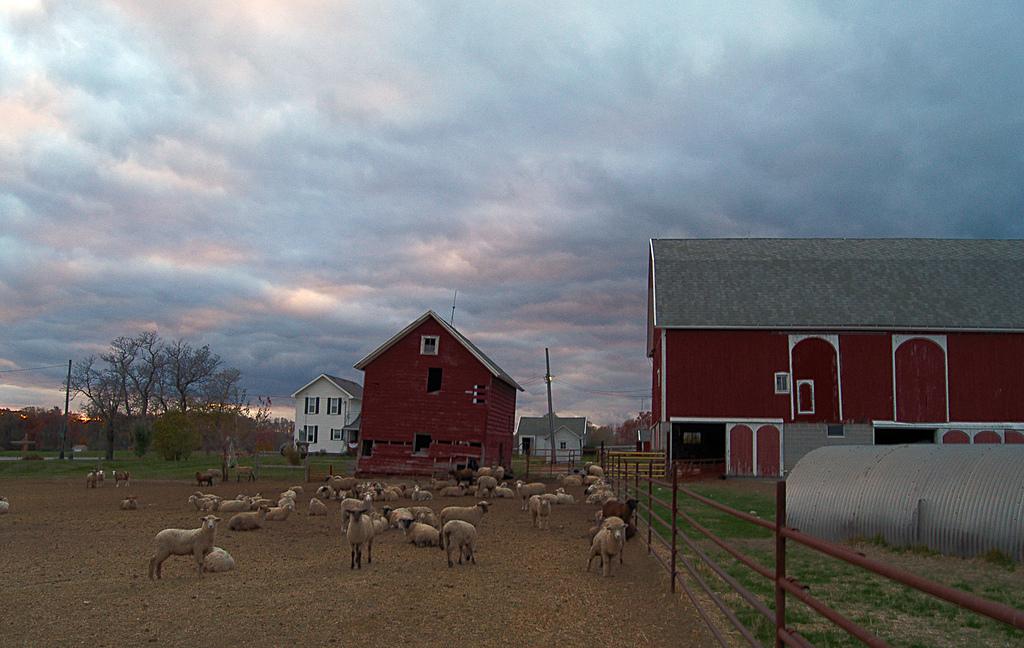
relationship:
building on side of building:
[353, 309, 525, 478] [336, 301, 511, 483]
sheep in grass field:
[112, 499, 251, 597] [28, 475, 629, 644]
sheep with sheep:
[213, 504, 268, 535] [228, 505, 271, 531]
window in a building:
[417, 332, 441, 361] [350, 306, 510, 475]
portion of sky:
[292, 293, 340, 320] [11, 12, 610, 306]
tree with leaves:
[158, 353, 215, 472] [197, 347, 217, 371]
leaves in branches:
[197, 347, 217, 371] [179, 369, 240, 408]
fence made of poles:
[624, 446, 990, 643] [655, 472, 789, 626]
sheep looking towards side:
[140, 513, 231, 578] [220, 546, 583, 637]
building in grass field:
[288, 373, 362, 458] [0, 475, 734, 648]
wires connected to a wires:
[9, 353, 102, 399] [58, 359, 71, 459]